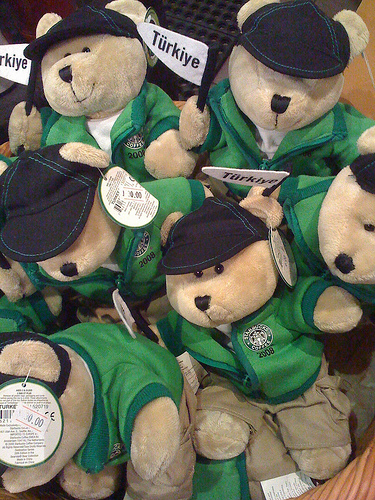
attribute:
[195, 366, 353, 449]
pants — brown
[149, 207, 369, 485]
bear — teddy bear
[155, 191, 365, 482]
animal — stuffed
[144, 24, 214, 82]
flag — black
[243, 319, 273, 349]
logo — green, black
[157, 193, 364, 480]
teddy bear — cute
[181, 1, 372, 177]
teddy bear — cute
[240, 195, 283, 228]
ear — bear's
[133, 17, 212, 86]
tag — white, black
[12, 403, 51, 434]
price tag — white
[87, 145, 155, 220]
tag — green, white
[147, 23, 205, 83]
letters — black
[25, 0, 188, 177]
teddy bear — cute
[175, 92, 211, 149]
paws — tan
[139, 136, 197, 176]
paws — tan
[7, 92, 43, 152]
paws — tan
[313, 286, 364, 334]
paws — tan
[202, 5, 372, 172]
animal — stuffed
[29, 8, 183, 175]
animal — stuffed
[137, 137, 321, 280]
shirt — white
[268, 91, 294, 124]
nose — black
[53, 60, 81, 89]
nose — black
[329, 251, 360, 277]
nose — black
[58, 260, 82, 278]
nose — black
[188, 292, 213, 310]
nose — black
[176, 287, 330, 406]
jacket — green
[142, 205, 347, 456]
animal — stuffed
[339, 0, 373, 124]
table — brown